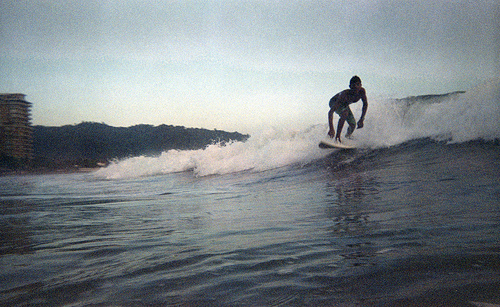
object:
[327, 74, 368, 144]
surfer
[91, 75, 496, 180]
wave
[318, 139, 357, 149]
surfboard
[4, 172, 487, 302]
water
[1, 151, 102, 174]
coastline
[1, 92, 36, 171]
building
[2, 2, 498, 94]
sky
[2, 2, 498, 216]
background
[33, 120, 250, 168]
mountain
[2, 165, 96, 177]
beach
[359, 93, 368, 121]
arm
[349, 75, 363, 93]
head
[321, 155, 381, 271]
shadow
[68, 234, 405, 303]
ripples